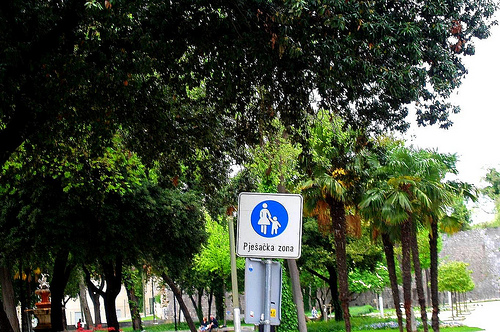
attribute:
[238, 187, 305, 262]
sign — white and blue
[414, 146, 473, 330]
tree — tall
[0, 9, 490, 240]
leaves — dark green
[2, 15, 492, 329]
trees — green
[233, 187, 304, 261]
signboard — white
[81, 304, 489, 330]
grass — green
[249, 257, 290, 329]
pole — gray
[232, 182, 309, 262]
sign — square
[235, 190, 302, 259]
sign — square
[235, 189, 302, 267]
sign — black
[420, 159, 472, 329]
palm tree — tall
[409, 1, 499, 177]
sky — bright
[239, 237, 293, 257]
letters — black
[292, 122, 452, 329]
palms — small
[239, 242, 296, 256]
polish language — polish 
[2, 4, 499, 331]
branches — big, green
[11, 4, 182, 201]
tree — big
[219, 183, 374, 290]
signboard — white, blue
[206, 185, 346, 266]
sign — white, blue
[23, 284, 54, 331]
water fountain — beige, red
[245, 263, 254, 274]
sticker — blue and white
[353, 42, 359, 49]
leaf — green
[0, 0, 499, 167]
tree — large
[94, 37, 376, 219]
palm trees — tall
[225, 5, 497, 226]
sky — overcast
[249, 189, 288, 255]
circle — blue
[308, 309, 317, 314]
t-shirt — light blue